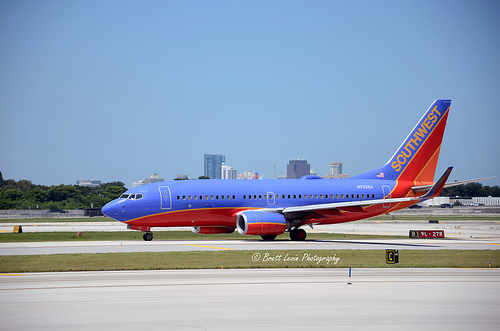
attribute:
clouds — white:
[56, 74, 195, 129]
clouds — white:
[239, 87, 311, 131]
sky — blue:
[0, 6, 500, 156]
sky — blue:
[150, 16, 380, 136]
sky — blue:
[0, 0, 500, 182]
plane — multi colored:
[99, 98, 456, 237]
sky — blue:
[180, 45, 310, 105]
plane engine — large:
[233, 204, 290, 242]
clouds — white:
[142, 70, 383, 140]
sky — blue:
[231, 18, 349, 80]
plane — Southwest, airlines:
[81, 98, 481, 238]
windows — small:
[278, 190, 293, 203]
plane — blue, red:
[75, 81, 455, 251]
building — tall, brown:
[285, 154, 315, 178]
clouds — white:
[0, 0, 500, 179]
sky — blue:
[4, 3, 498, 207]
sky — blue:
[188, 40, 370, 149]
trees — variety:
[0, 169, 130, 211]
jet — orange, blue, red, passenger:
[102, 96, 451, 245]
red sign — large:
[407, 230, 447, 239]